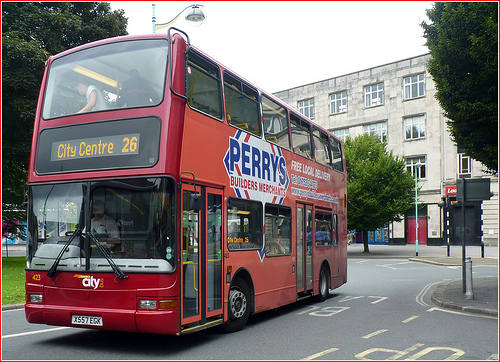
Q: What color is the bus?
A: Red.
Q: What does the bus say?
A: City Centre 26.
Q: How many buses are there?
A: One.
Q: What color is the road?
A: Black.